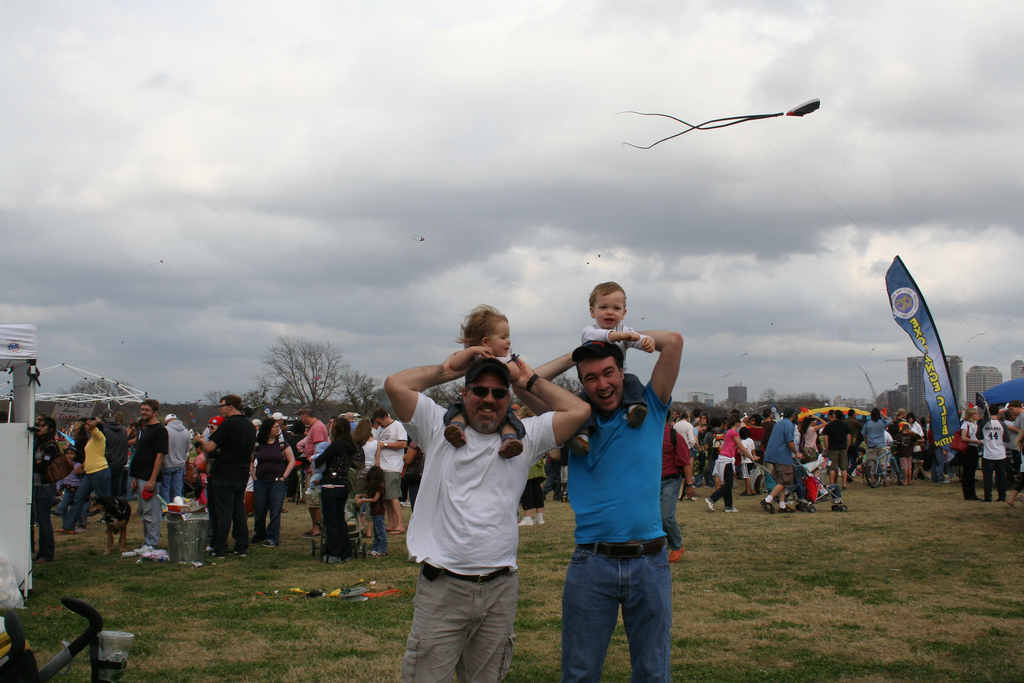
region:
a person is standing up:
[519, 311, 706, 666]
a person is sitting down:
[554, 266, 663, 453]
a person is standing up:
[350, 341, 581, 667]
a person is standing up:
[356, 404, 415, 519]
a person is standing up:
[308, 393, 365, 565]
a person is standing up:
[260, 393, 303, 550]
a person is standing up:
[93, 384, 173, 563]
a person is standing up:
[72, 405, 117, 543]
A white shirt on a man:
[396, 389, 568, 570]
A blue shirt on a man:
[550, 385, 671, 545]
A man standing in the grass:
[514, 278, 692, 680]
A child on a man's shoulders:
[573, 275, 649, 447]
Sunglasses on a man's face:
[463, 379, 505, 408]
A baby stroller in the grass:
[791, 442, 848, 520]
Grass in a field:
[7, 461, 1016, 673]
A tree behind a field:
[250, 332, 377, 406]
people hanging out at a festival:
[184, 390, 249, 561]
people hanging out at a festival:
[307, 408, 353, 555]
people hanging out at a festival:
[359, 396, 405, 536]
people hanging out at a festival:
[896, 413, 913, 477]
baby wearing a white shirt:
[569, 282, 649, 453]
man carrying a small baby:
[512, 277, 680, 677]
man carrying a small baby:
[387, 303, 591, 680]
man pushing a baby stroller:
[760, 407, 847, 513]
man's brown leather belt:
[577, 537, 667, 557]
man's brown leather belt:
[418, 563, 508, 582]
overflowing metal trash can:
[163, 495, 212, 563]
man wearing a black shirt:
[127, 395, 169, 561]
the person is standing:
[59, 430, 82, 513]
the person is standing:
[133, 404, 182, 576]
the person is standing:
[197, 382, 264, 559]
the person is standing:
[308, 407, 360, 584]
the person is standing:
[406, 413, 534, 673]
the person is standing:
[536, 315, 673, 671]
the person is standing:
[697, 407, 754, 509]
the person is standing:
[816, 385, 878, 496]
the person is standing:
[964, 404, 1019, 481]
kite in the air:
[612, 76, 837, 168]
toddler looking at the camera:
[568, 275, 658, 463]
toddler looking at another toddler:
[436, 294, 542, 465]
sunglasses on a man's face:
[464, 382, 513, 401]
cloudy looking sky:
[3, 3, 1022, 434]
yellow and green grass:
[15, 476, 1022, 676]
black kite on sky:
[608, 97, 825, 155]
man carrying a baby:
[517, 275, 688, 680]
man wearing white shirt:
[383, 350, 592, 680]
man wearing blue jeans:
[514, 328, 689, 680]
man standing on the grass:
[124, 388, 169, 562]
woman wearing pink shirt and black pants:
[702, 414, 748, 516]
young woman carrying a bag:
[27, 412, 65, 564]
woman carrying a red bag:
[949, 396, 976, 502]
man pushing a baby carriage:
[754, 407, 846, 513]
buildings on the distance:
[712, 354, 1020, 409]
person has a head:
[463, 357, 511, 427]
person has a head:
[576, 344, 625, 409]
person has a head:
[593, 280, 628, 323]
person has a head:
[466, 309, 511, 352]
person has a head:
[330, 419, 351, 440]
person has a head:
[216, 388, 242, 409]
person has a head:
[143, 398, 160, 422]